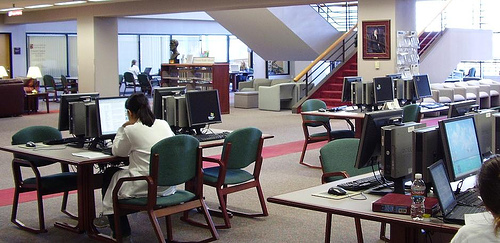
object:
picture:
[359, 18, 399, 63]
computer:
[95, 96, 155, 156]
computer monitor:
[436, 112, 485, 183]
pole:
[76, 15, 123, 100]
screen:
[446, 109, 492, 176]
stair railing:
[296, 20, 354, 112]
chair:
[204, 128, 282, 239]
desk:
[292, 105, 373, 139]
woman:
[98, 87, 189, 227]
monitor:
[380, 120, 424, 180]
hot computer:
[393, 104, 498, 204]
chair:
[298, 99, 355, 170]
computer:
[353, 109, 408, 197]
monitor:
[440, 119, 483, 178]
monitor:
[422, 161, 454, 211]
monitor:
[370, 76, 396, 101]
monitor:
[94, 93, 139, 135]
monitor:
[342, 75, 360, 100]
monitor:
[142, 66, 151, 73]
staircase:
[306, 62, 353, 110]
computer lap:
[12, 14, 497, 232]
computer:
[59, 93, 99, 148]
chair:
[10, 125, 82, 236]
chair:
[113, 133, 223, 243]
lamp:
[24, 64, 44, 92]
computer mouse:
[327, 186, 349, 196]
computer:
[438, 115, 486, 210]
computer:
[183, 88, 230, 145]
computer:
[373, 75, 396, 111]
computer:
[412, 74, 434, 100]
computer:
[425, 158, 492, 225]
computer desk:
[0, 126, 273, 235]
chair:
[317, 136, 380, 243]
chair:
[179, 126, 271, 231]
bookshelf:
[160, 62, 230, 114]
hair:
[125, 92, 157, 127]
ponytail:
[134, 104, 157, 127]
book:
[371, 193, 439, 217]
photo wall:
[357, 22, 395, 63]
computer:
[153, 86, 186, 120]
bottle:
[409, 172, 426, 222]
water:
[408, 171, 428, 220]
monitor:
[183, 89, 225, 129]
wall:
[344, 0, 400, 80]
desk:
[270, 158, 483, 241]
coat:
[97, 119, 177, 217]